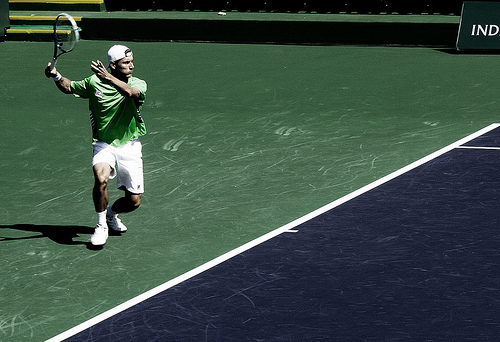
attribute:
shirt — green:
[68, 63, 152, 153]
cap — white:
[93, 39, 149, 71]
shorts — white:
[70, 142, 158, 216]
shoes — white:
[80, 219, 134, 255]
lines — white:
[215, 205, 334, 263]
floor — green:
[270, 161, 354, 225]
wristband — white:
[50, 71, 72, 84]